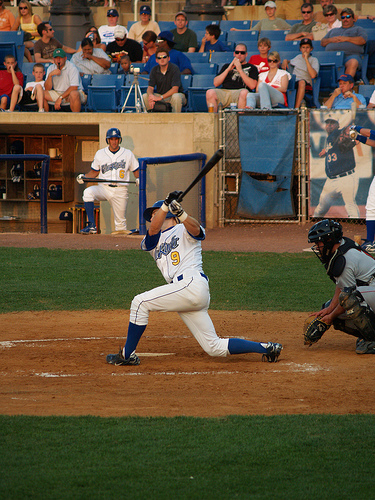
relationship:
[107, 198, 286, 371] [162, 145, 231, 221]
he swinging bat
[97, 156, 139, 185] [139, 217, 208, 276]
number on jersey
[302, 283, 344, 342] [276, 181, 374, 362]
arms of catcher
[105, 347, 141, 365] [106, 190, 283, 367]
foot of he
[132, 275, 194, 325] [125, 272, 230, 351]
stripe on pants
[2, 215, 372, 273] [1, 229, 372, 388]
dirt of field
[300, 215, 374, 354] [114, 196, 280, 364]
catcher behind batter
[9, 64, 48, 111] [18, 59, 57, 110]
child slouching in seat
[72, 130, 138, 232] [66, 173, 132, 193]
baseball player holding bat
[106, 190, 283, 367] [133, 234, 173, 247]
he looking over shoulder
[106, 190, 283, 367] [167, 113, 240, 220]
he swinging bat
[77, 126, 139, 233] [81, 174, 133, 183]
man holding bat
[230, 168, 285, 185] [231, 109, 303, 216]
tear in tarp